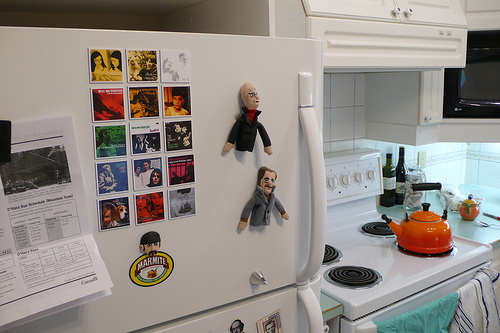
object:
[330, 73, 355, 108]
tile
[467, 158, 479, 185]
tile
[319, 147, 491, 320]
stove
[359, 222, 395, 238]
burners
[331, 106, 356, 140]
tile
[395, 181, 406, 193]
label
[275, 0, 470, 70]
cabinet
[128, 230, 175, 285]
magnet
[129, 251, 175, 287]
marmite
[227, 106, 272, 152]
suit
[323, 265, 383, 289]
burner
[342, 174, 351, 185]
knob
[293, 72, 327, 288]
handle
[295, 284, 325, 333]
handle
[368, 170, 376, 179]
knob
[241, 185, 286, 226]
coat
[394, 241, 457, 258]
burner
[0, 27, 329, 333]
door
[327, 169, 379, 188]
nobs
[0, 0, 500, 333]
kitchen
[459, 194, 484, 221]
bowl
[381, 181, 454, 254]
kettle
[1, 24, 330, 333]
freezer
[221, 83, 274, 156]
fridge magnet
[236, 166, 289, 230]
fridge magnet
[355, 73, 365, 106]
tile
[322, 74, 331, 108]
tile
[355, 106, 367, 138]
tile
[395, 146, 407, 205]
bottle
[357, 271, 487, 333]
oven handle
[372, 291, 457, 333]
kitchen towel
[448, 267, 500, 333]
kitchen towel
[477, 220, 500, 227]
spoon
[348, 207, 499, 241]
counter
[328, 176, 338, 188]
knob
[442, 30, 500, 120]
microwave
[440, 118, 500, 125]
shelf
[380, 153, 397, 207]
bottle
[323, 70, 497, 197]
wall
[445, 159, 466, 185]
tile